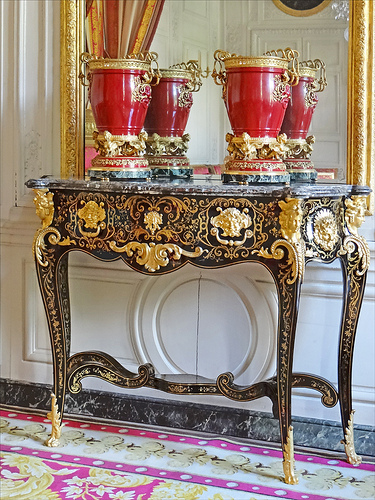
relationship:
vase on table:
[82, 61, 153, 149] [27, 181, 350, 475]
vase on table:
[215, 51, 296, 165] [27, 181, 350, 475]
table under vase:
[27, 181, 350, 475] [82, 61, 153, 149]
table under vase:
[27, 181, 350, 475] [215, 51, 296, 165]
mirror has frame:
[66, 8, 82, 57] [49, 14, 79, 72]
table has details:
[27, 181, 350, 475] [195, 199, 259, 250]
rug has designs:
[87, 451, 161, 491] [113, 462, 148, 483]